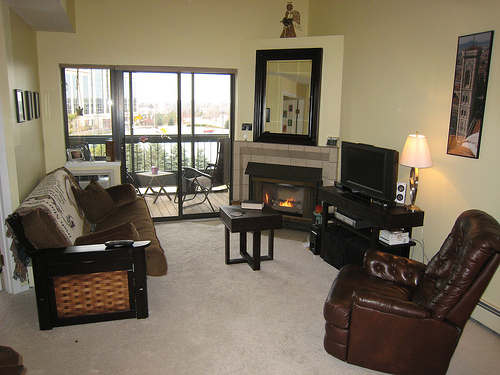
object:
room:
[0, 1, 499, 374]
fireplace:
[243, 161, 322, 222]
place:
[263, 185, 304, 215]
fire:
[278, 196, 296, 207]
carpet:
[0, 217, 499, 373]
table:
[219, 199, 283, 271]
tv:
[340, 140, 399, 212]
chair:
[322, 209, 499, 375]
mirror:
[253, 47, 324, 146]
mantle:
[232, 141, 338, 161]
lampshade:
[398, 134, 432, 169]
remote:
[104, 239, 135, 248]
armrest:
[26, 239, 151, 258]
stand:
[316, 185, 425, 270]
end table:
[26, 238, 151, 331]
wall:
[345, 0, 447, 144]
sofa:
[3, 166, 168, 283]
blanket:
[5, 166, 96, 283]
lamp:
[399, 131, 434, 214]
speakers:
[393, 182, 406, 206]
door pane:
[179, 70, 236, 219]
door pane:
[117, 69, 180, 221]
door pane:
[60, 66, 116, 157]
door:
[118, 69, 233, 221]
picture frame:
[446, 30, 494, 159]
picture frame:
[24, 90, 35, 121]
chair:
[173, 136, 231, 212]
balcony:
[60, 63, 238, 222]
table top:
[219, 203, 283, 220]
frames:
[14, 89, 26, 124]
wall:
[1, 29, 46, 222]